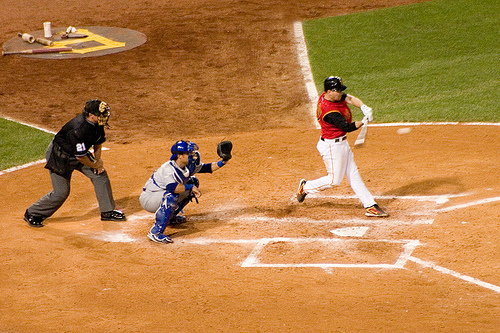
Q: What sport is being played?
A: Baseball.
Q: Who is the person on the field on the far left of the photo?
A: Umpire.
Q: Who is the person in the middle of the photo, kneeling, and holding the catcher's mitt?
A: Catcher.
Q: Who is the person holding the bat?
A: Batter.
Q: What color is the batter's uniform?
A: Red, black and white.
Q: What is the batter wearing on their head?
A: Helmet.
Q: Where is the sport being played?
A: Baseball field.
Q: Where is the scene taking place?
A: At the baseball field.